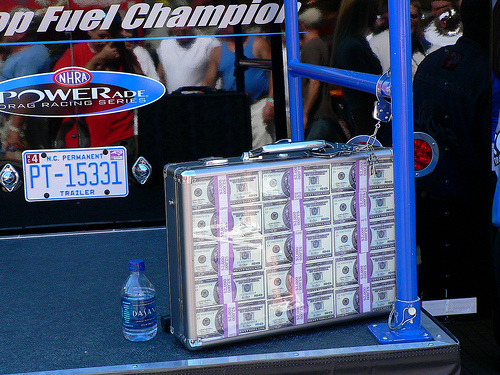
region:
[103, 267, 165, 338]
teh bottle is on the table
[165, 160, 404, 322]
the briefcase is full of money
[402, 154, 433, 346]
the metal pole is blue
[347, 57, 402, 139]
the handcuffs are on the metal pole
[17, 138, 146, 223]
the number plate is white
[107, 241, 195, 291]
the bottletop is blue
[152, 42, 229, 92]
the mans shirt is white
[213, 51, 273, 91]
the mans shirt is blue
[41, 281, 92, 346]
the surface is grey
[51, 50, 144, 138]
his shirt is red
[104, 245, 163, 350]
a dasani water bottle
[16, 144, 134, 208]
a trailer license plate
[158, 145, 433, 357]
a suitcase of money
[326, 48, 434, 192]
handcuffs holding the suitcase of money to a pole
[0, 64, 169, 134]
powerade logo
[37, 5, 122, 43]
the word fuel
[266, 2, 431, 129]
blue poles with handcuff attached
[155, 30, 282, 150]
reflection of people and the suitcase of money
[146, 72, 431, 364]
the suitcase of money and its reflection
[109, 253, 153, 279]
cap on the bottle of water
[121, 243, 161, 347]
small dasani water bottle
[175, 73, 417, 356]
clear briefcase filled with money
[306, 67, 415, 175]
silver handcuffs securing briefcase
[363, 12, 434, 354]
blue pole to which briefcase is attached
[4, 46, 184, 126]
advertisement for the powerade drag racing series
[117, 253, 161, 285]
blue cap of dasani water bottle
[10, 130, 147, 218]
blue and white license plate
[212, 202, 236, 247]
purple and white paper money bands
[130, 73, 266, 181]
reflection of briefcase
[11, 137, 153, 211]
blue lettering on white license plate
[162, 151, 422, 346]
A suitcase full of money.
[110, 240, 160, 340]
A small bottle of water.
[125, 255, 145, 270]
The bottle cap is blue.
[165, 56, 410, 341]
The suitcase is secured to the metal rail.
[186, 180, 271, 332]
The money is separated into different bundles using a purple piece of paper.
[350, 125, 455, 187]
The vehicle's brake lights.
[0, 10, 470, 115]
The reflection of a crowd can be seen on the vehicle's exterior.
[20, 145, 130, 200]
A white license plate.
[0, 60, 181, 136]
A corporate sponsor's logo.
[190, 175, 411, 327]
A suitcase full of twenty dollar bills.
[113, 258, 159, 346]
A small bottle of water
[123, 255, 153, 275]
The blue cap on a bottle of water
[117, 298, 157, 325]
The label on a water bottle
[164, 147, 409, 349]
A suitcase of money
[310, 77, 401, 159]
A pair of handcuffs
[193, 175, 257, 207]
A dollar bill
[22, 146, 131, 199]
A metal license plate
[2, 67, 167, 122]
A PowerAde advertisement on glass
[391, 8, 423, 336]
A blue metal pole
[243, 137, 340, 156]
The handle of a suitcase